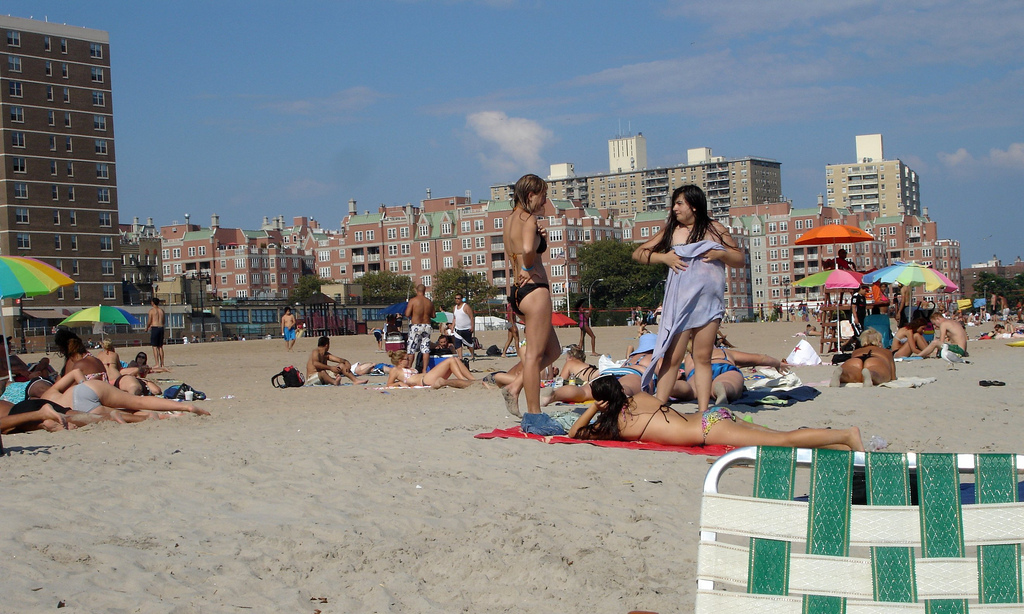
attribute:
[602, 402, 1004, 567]
chair back — green, white, striped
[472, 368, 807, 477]
beach towel — red